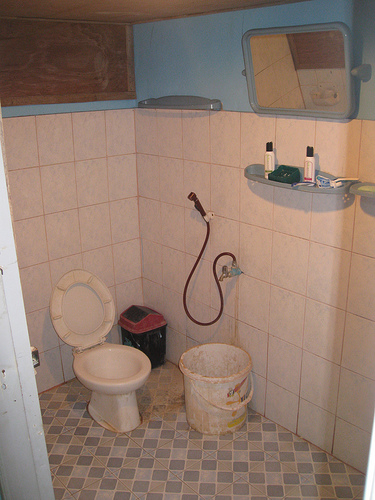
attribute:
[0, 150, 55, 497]
bathroom door — white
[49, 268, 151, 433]
toilet — dirty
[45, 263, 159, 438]
toilet — white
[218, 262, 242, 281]
faucet — water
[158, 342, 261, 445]
bucket — dirty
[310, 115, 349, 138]
ground — black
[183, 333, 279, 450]
bucket — white, plastic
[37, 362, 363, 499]
floor — tiled, blue, tan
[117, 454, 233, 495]
tiles — white, grey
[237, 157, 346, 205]
shelf — blue, plastic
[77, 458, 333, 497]
tile — checkered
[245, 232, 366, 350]
tiles — white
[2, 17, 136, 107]
plank — wooden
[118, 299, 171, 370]
waste bin — red and black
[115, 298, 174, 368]
can — red